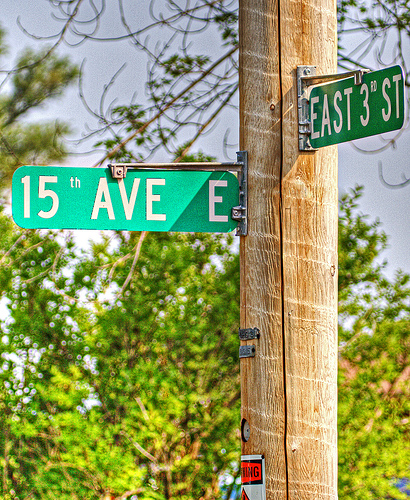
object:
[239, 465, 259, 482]
text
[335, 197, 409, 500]
trees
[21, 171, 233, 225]
text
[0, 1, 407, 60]
sky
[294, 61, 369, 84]
hanger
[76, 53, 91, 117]
branches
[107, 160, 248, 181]
bracket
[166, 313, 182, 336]
leaves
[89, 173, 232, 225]
ave e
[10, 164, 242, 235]
sign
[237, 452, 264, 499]
sign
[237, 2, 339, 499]
pole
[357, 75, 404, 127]
3rd st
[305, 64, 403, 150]
sign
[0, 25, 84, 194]
tree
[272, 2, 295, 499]
crack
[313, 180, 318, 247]
scratches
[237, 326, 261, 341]
clasps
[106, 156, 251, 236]
holder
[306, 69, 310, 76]
screw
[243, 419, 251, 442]
screw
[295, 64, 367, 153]
attachment